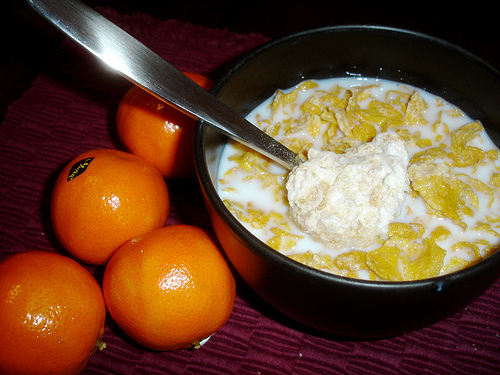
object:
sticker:
[66, 156, 95, 181]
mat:
[0, 1, 499, 374]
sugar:
[285, 130, 411, 247]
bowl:
[192, 21, 499, 343]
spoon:
[27, 0, 303, 170]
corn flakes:
[218, 187, 238, 192]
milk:
[216, 75, 500, 282]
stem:
[95, 340, 105, 352]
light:
[157, 260, 198, 295]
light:
[262, 242, 438, 294]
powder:
[256, 129, 305, 170]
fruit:
[0, 248, 104, 375]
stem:
[190, 341, 200, 350]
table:
[0, 0, 500, 375]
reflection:
[77, 0, 151, 87]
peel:
[101, 222, 237, 352]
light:
[103, 193, 122, 211]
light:
[162, 119, 181, 135]